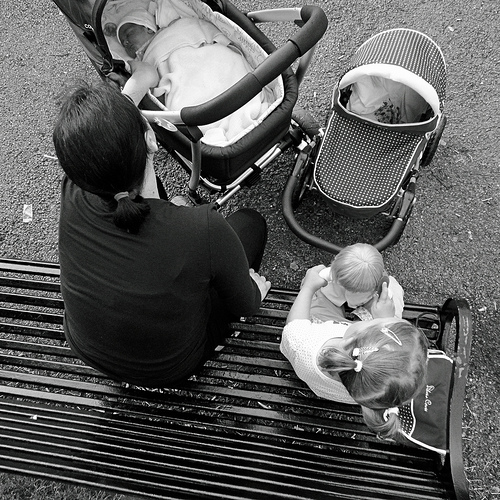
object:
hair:
[317, 322, 430, 448]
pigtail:
[319, 348, 357, 371]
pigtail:
[364, 410, 406, 445]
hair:
[329, 242, 384, 295]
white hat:
[116, 10, 157, 47]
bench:
[0, 255, 473, 500]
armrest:
[437, 296, 473, 498]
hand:
[126, 59, 159, 87]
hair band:
[354, 360, 363, 373]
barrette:
[380, 327, 402, 346]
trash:
[22, 203, 33, 224]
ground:
[1, 0, 500, 499]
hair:
[52, 79, 151, 235]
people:
[51, 78, 427, 440]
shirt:
[278, 318, 358, 404]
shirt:
[59, 174, 262, 388]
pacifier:
[104, 22, 118, 36]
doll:
[317, 243, 388, 320]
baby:
[116, 8, 159, 60]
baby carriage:
[53, 0, 328, 210]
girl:
[52, 60, 271, 387]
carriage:
[281, 27, 446, 255]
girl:
[279, 264, 428, 444]